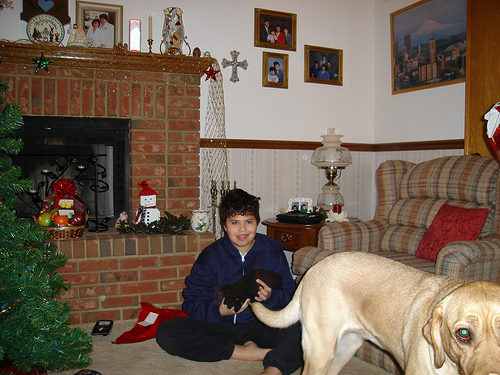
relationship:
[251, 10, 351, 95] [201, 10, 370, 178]
photos on wall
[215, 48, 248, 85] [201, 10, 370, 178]
cross on wall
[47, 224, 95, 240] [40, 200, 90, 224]
basket has fruit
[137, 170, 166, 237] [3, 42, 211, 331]
decoration on fireplace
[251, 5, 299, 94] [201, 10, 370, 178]
pictures on wall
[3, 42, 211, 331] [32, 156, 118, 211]
fireplace not lit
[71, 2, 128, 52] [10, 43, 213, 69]
picture on mantel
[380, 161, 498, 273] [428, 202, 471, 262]
chair has cushion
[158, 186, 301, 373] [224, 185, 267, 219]
boy has hair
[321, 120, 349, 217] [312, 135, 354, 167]
lamp has shade